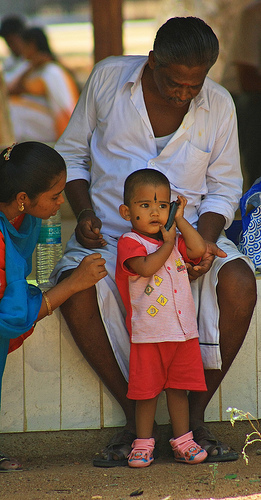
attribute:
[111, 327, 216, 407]
pants — red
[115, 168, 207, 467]
child — small, young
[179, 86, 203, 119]
ground —  brown,  dirt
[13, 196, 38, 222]
earring — gold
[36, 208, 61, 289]
bottle — plastic, water, for water,  clear 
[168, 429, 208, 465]
shoes —  PINK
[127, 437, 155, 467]
shoes —  PINK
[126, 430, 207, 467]
shoes —  PINK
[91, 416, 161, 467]
sandal — brown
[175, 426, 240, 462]
sandal — brown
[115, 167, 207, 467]
kid — standing, little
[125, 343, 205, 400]
shorts —  BABY'S,   RED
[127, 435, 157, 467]
shoe — hers,  pink and blue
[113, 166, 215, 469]
child — small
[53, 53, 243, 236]
shirt — white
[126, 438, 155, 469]
shoes —   TINY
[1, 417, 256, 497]
ground — dirt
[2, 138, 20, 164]
hair tie — colorful